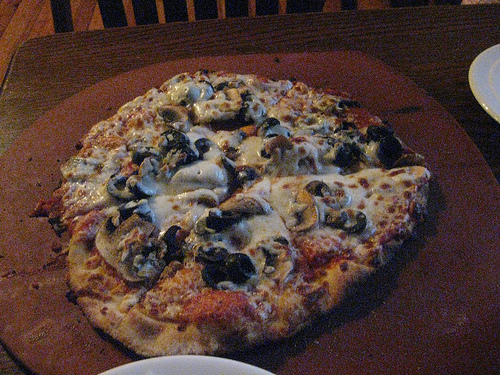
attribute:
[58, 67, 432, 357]
pizza — red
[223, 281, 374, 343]
pizza crust — cooked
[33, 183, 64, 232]
sauce — pizza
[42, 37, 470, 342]
pizza — cheese and meat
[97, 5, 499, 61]
brown table — round 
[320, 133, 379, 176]
olive — black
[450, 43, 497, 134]
plate — white , yellow 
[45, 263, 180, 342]
pizza — thin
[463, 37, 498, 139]
plate — white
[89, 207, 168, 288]
mushroom — large, brown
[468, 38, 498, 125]
plate edge — white ceramic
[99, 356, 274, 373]
plate edge — white ceramic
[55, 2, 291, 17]
wooden — rods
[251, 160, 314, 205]
cheese — melted, browned, mozzarella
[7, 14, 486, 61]
brown table — brown 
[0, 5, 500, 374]
table — wooden 